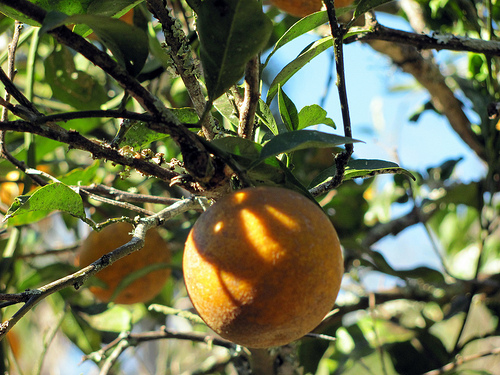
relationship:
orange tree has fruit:
[2, 0, 499, 374] [183, 191, 345, 356]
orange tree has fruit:
[2, 0, 499, 374] [78, 220, 169, 304]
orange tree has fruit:
[2, 0, 499, 374] [271, 0, 351, 15]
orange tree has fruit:
[2, 0, 499, 374] [66, 9, 135, 39]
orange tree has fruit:
[2, 0, 499, 374] [0, 169, 27, 211]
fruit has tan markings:
[183, 191, 345, 351] [201, 214, 327, 351]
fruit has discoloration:
[78, 220, 169, 304] [121, 237, 169, 297]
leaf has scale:
[196, 2, 276, 128] [204, 17, 245, 85]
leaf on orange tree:
[246, 123, 361, 160] [2, 0, 499, 374]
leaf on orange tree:
[34, 4, 156, 88] [2, 0, 499, 374]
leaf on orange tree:
[263, 7, 371, 73] [2, 0, 499, 374]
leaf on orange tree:
[53, 59, 247, 189] [2, 0, 499, 374]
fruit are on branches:
[183, 191, 345, 351] [0, 1, 499, 372]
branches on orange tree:
[5, 2, 277, 184] [2, 0, 499, 374]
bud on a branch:
[156, 152, 168, 165] [1, 67, 196, 193]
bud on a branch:
[138, 146, 154, 162] [1, 67, 196, 193]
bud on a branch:
[167, 156, 182, 171] [1, 67, 196, 193]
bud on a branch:
[120, 143, 135, 157] [1, 67, 196, 193]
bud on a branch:
[70, 280, 85, 292] [1, 67, 196, 193]